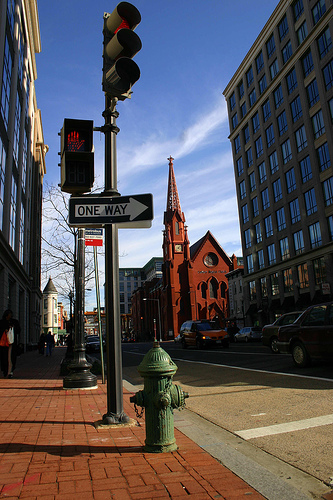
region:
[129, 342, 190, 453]
Green fire hydrant.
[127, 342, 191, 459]
Fire hydrant on brick sidewalk.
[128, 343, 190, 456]
Fire hydrant on red brick sidewalk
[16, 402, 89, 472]
Red brick sidewalk.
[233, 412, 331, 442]
White line painted on street.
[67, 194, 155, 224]
One way traffic sign.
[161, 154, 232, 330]
Red brick church.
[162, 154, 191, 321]
Church steeple with clock.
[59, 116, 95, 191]
Do not walk indicator.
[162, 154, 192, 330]
Tall red brick church steeple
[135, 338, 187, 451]
green fire hydrant on the roadside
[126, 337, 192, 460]
a green fire hydrant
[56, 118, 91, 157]
orange hand signal sign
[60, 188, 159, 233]
one way street sign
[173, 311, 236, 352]
an orange van in the street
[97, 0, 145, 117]
a three light traffic light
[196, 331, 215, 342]
right turn signal on the orange van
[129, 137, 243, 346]
a large orange church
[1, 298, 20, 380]
a woman holding a white bag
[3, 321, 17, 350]
the white bag in the woman's hand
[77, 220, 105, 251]
the sign behind the one way sign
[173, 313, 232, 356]
an orange taxi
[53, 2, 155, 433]
a traffic light on a black pole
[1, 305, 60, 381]
people walking on sidewalk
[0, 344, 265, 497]
a brick paved sidewalk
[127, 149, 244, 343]
a red brick church with tall steeple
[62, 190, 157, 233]
a black and white sign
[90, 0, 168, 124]
the traffic light is red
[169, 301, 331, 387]
three cars driving on street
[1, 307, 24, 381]
person holding a red bag and a white bag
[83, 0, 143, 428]
Traffic light on a pole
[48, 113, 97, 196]
the cross walk sign is red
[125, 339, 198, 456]
a green fire hydrant on sidewalk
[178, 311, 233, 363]
a orange minivan in the street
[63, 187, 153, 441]
a one way sign on a post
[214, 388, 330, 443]
the street has white lines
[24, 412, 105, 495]
the sidewalk is red brick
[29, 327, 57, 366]
people walking on the sidewalk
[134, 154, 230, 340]
a red brick church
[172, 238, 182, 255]
the church tower has a clock